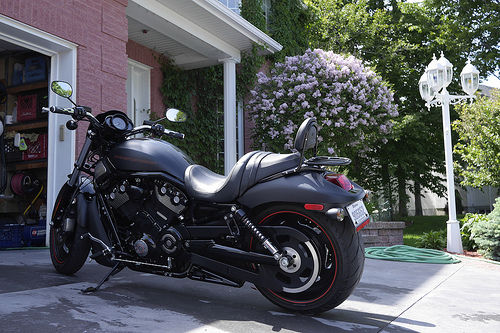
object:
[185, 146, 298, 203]
seat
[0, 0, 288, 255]
house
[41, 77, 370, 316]
motorcycle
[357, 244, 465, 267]
hose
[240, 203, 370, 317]
tires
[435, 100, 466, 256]
lamp post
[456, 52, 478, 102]
lamps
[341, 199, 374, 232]
license plate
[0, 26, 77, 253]
garage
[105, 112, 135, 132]
gauges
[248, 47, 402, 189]
lilac bush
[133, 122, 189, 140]
motorcycle handlebar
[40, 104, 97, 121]
motorcycle handlebar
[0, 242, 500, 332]
driveway